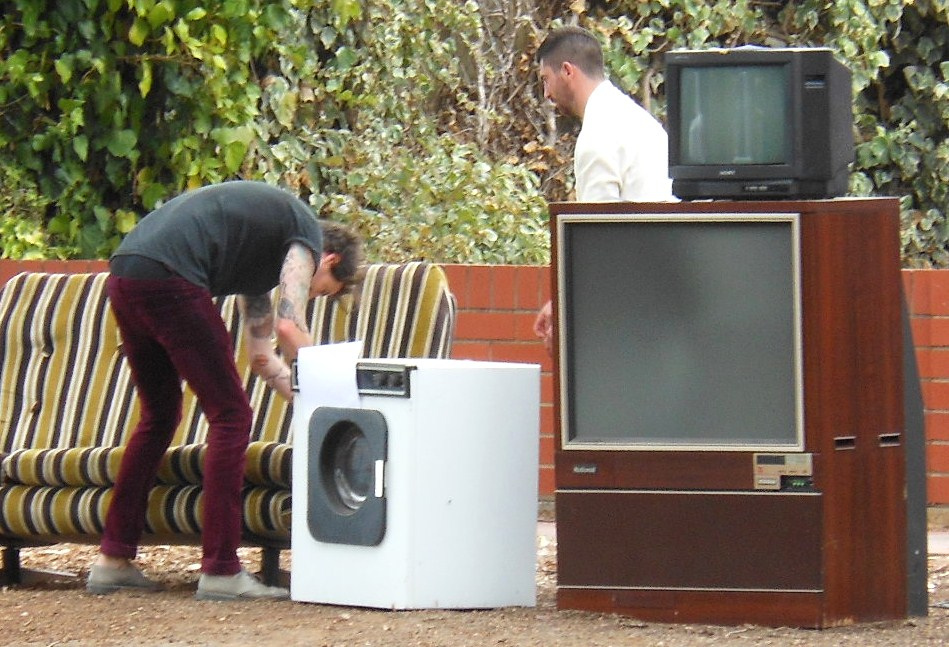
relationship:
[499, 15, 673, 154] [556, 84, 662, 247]
man has a shirt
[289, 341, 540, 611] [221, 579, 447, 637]
dryer on ground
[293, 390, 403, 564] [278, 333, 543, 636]
door of washing machine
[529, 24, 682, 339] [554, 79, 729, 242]
man wearing top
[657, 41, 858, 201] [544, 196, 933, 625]
television on television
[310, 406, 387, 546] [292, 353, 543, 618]
door to dryer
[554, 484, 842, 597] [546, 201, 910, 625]
speaker on television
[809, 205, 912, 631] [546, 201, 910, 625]
side of television